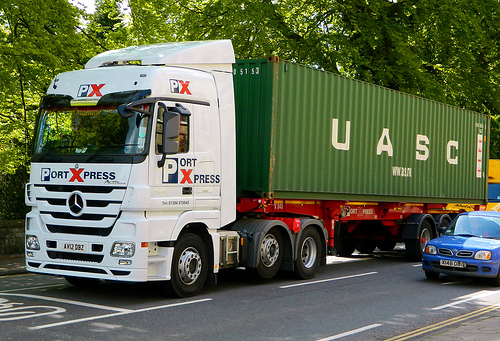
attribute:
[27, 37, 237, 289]
front — white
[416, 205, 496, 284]
sabb — blue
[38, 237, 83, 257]
plate — european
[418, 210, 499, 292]
car — blue 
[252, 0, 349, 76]
tree branch — leafy, green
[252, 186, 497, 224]
bed — red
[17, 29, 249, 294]
truck cab — white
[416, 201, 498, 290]
car — blue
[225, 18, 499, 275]
trailer — green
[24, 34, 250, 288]
cab — white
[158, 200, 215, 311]
wheel — black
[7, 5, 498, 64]
tree — green, leafy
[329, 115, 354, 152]
u — white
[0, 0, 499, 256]
trees — tall 